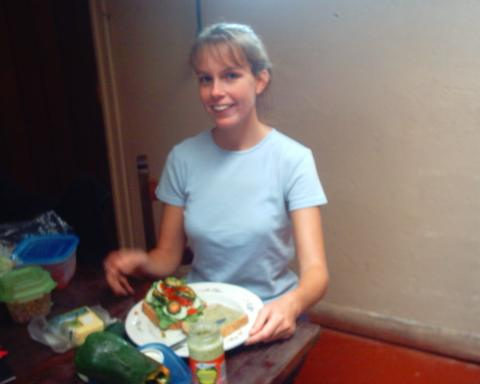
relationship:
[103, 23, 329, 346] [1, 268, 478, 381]
lady sitting at table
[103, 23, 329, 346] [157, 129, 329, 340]
lady wearing shirt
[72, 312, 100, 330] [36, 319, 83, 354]
cheese in bag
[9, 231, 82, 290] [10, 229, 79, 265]
container has lid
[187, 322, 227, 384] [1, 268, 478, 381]
jar on table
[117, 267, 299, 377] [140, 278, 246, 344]
plate has food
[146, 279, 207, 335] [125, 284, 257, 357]
bread on plate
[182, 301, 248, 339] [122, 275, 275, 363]
bread on plate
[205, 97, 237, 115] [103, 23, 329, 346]
mouth of lady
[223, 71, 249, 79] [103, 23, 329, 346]
eye of lady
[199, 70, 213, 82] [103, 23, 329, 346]
eye of lady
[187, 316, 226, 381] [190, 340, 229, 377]
jar has substance